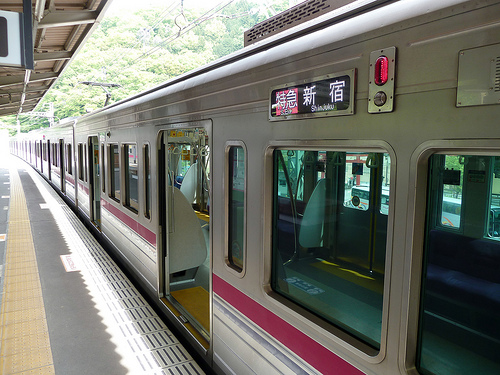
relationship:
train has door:
[6, 2, 499, 373] [155, 117, 222, 368]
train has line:
[6, 2, 499, 373] [212, 271, 366, 374]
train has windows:
[6, 2, 499, 373] [257, 132, 402, 366]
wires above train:
[3, 1, 243, 133] [6, 2, 499, 373]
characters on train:
[272, 89, 299, 117] [6, 2, 499, 373]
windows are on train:
[257, 132, 402, 366] [6, 2, 499, 373]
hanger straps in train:
[170, 143, 181, 157] [6, 2, 499, 373]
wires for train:
[3, 1, 243, 133] [6, 2, 499, 373]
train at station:
[6, 2, 499, 373] [0, 0, 212, 373]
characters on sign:
[272, 89, 299, 117] [265, 68, 357, 122]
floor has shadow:
[3, 151, 204, 372] [2, 158, 129, 374]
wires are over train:
[3, 1, 243, 133] [6, 2, 499, 373]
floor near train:
[3, 151, 204, 372] [6, 2, 499, 373]